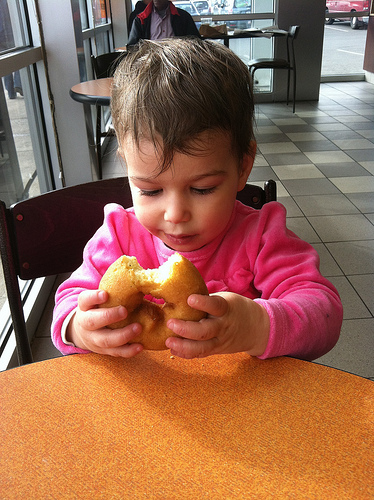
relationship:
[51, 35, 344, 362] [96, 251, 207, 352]
girl holding donut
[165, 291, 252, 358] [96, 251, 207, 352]
hand holding donut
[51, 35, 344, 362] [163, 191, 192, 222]
girl has nose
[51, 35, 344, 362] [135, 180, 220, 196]
girl has eyes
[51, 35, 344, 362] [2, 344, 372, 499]
girl sitting in front of table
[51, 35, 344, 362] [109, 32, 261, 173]
girl has hair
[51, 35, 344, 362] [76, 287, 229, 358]
girl has fingers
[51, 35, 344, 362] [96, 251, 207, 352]
girl eating donut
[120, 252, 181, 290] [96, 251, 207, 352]
bite on top of donut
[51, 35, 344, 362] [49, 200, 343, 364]
girl wearing shirt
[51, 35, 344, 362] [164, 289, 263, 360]
girl has hand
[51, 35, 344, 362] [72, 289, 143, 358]
girl has hand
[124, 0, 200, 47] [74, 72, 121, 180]
man sitting at table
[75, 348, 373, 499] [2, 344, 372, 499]
shadow cast on table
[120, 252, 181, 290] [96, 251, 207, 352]
bite missing on donut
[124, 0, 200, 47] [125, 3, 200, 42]
man wearing jacket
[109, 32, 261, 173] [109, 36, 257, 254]
hair on top of head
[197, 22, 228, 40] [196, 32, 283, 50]
paper bag on top of table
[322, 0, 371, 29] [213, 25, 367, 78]
truck outside in parking lot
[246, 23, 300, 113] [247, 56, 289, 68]
chair has cushion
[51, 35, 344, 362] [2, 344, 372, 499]
girl sitting at table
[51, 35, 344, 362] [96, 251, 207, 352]
girl looking at donut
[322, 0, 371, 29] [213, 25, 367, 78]
truck parked in parking lot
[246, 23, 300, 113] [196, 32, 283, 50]
chair next to table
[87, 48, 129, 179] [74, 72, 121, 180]
chair next to table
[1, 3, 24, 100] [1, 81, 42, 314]
pedestrian walking on sidewalk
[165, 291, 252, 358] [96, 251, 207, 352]
hand gripping donut